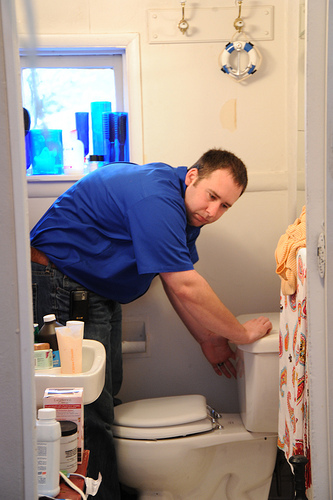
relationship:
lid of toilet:
[110, 391, 220, 442] [110, 306, 298, 497]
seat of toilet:
[106, 387, 225, 471] [110, 306, 298, 497]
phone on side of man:
[66, 286, 94, 327] [33, 146, 275, 499]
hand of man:
[236, 312, 273, 350] [33, 146, 275, 499]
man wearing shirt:
[33, 146, 275, 499] [33, 154, 207, 312]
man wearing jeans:
[33, 146, 275, 499] [30, 229, 138, 498]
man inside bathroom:
[33, 146, 275, 499] [1, 4, 332, 499]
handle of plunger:
[286, 454, 313, 499] [282, 450, 316, 499]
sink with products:
[56, 446, 94, 499] [33, 306, 110, 498]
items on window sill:
[18, 96, 130, 172] [26, 167, 120, 207]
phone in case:
[66, 286, 94, 327] [67, 282, 92, 318]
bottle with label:
[34, 313, 85, 372] [63, 446, 80, 471]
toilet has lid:
[110, 306, 298, 497] [110, 391, 220, 442]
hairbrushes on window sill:
[102, 108, 126, 168] [26, 167, 120, 207]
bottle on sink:
[34, 313, 85, 372] [56, 446, 94, 499]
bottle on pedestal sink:
[37, 313, 72, 368] [37, 332, 110, 408]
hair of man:
[186, 146, 254, 199] [33, 146, 275, 499]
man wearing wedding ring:
[33, 146, 275, 499] [216, 359, 226, 371]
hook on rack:
[177, 17, 190, 33] [167, 1, 206, 15]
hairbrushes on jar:
[102, 108, 126, 168] [96, 108, 135, 169]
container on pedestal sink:
[53, 323, 78, 374] [37, 332, 110, 408]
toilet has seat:
[110, 306, 298, 497] [106, 387, 225, 471]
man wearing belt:
[33, 146, 275, 499] [32, 246, 55, 272]